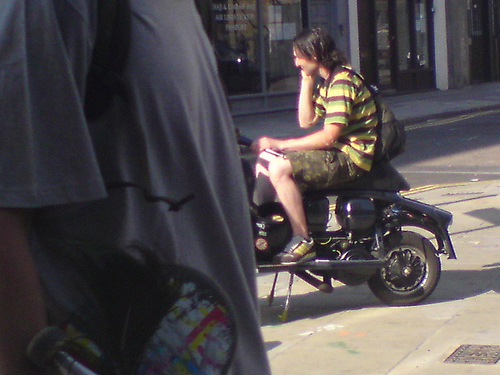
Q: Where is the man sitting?
A: Motorcycle.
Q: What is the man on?
A: Motorcycle.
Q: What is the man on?
A: Motorcycle.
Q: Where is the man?
A: On motorcycle.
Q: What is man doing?
A: Sitting.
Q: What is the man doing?
A: Talking.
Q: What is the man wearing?
A: Shirt.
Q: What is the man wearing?
A: Shirt.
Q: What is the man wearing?
A: Shorts.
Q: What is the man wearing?
A: Shoes.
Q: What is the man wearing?
A: Bag.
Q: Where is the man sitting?
A: Bike.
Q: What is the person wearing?
A: Shirt.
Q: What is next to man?
A: Bouse.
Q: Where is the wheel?
A: On the bike.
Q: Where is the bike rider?
A: On the bike.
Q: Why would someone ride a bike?
A: Transportation.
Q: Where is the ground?
A: Under the bike.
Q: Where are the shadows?
A: On the ground.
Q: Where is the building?
A: Behind the bike.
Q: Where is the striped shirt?
A: On the biker.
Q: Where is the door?
A: On the building.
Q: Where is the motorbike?
A: Under the biker.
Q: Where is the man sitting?
A: On the motorbike.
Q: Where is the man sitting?
A: Motorcycle.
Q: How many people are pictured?
A: 2.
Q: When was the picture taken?
A: Daytime.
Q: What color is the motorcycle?
A: Black.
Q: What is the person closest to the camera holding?
A: Skateboard.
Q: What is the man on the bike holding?
A: Cellphone.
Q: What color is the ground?
A: Gray.